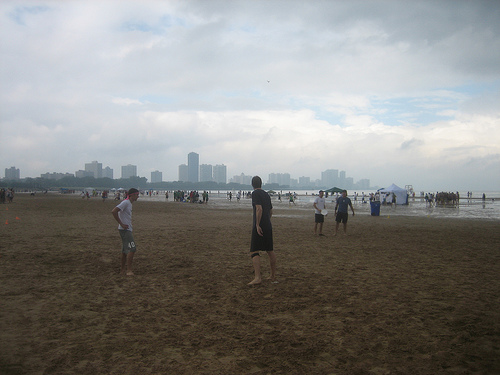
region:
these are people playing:
[105, 171, 356, 271]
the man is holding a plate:
[306, 190, 331, 230]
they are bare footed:
[90, 255, 285, 272]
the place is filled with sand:
[7, 291, 497, 366]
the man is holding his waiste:
[111, 201, 124, 233]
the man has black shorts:
[252, 223, 267, 244]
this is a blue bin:
[365, 199, 386, 214]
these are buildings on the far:
[158, 148, 226, 184]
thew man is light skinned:
[252, 261, 255, 265]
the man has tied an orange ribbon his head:
[125, 188, 139, 196]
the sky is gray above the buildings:
[5, 3, 496, 198]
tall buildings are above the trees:
[3, 146, 388, 193]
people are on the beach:
[3, 170, 498, 286]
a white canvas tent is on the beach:
[370, 180, 412, 211]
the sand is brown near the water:
[2, 190, 495, 371]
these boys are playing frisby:
[112, 175, 357, 290]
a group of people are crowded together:
[420, 186, 463, 208]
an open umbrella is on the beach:
[325, 182, 346, 202]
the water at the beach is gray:
[103, 185, 498, 215]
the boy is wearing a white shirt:
[113, 187, 142, 284]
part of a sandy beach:
[328, 215, 388, 353]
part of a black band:
[243, 247, 268, 264]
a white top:
[123, 209, 133, 227]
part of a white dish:
[320, 203, 328, 217]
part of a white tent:
[394, 185, 409, 202]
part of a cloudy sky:
[241, 99, 309, 145]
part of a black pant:
[260, 235, 270, 247]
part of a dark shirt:
[261, 195, 271, 216]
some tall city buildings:
[176, 158, 219, 188]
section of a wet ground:
[433, 200, 465, 213]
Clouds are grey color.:
[41, 31, 292, 125]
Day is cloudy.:
[18, 99, 402, 304]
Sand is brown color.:
[139, 288, 259, 337]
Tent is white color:
[371, 176, 414, 210]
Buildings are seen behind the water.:
[13, 159, 380, 194]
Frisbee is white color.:
[316, 206, 343, 231]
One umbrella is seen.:
[328, 181, 345, 199]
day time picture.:
[6, 112, 476, 339]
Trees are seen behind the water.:
[26, 179, 256, 194]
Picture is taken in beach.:
[12, 63, 484, 326]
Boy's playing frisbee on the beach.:
[99, 177, 391, 279]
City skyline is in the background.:
[5, 131, 426, 196]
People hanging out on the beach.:
[38, 157, 479, 247]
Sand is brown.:
[28, 240, 452, 359]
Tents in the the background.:
[274, 173, 468, 215]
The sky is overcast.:
[40, 48, 457, 139]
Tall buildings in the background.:
[20, 132, 366, 189]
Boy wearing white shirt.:
[71, 178, 196, 270]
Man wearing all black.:
[241, 157, 293, 288]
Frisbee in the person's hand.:
[302, 185, 332, 237]